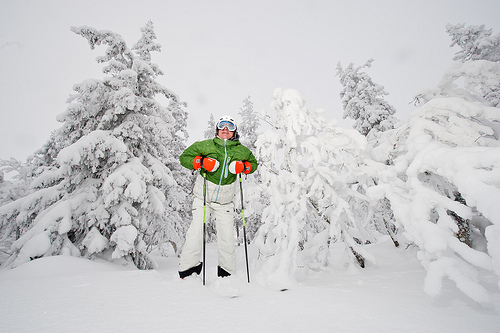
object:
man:
[180, 116, 258, 279]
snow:
[0, 19, 497, 332]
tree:
[0, 23, 196, 271]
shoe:
[178, 262, 205, 279]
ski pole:
[237, 165, 251, 282]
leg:
[215, 203, 238, 279]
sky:
[1, 0, 498, 159]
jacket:
[180, 141, 258, 204]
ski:
[278, 286, 291, 295]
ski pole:
[199, 165, 210, 285]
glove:
[228, 160, 253, 174]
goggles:
[218, 119, 235, 131]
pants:
[177, 198, 239, 280]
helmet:
[216, 116, 239, 124]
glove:
[191, 155, 219, 172]